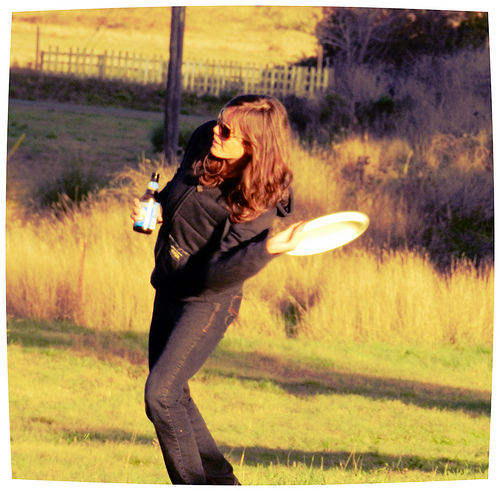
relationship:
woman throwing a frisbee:
[127, 91, 374, 486] [285, 211, 370, 258]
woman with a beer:
[127, 91, 374, 486] [130, 171, 162, 237]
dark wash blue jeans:
[177, 328, 199, 343] [143, 282, 247, 489]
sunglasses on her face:
[210, 114, 249, 141] [205, 113, 243, 162]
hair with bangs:
[189, 89, 295, 223] [213, 104, 252, 132]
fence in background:
[26, 33, 345, 101] [13, 6, 490, 275]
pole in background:
[156, 5, 188, 163] [13, 6, 490, 275]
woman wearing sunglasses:
[127, 91, 374, 486] [210, 114, 249, 141]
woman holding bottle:
[127, 91, 374, 486] [130, 171, 162, 237]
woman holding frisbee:
[127, 91, 374, 486] [285, 211, 370, 258]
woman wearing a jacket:
[127, 91, 374, 486] [148, 118, 282, 303]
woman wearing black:
[127, 91, 374, 486] [189, 189, 232, 262]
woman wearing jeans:
[127, 91, 374, 486] [143, 282, 247, 489]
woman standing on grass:
[127, 91, 374, 486] [7, 311, 498, 483]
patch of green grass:
[7, 98, 158, 193] [7, 311, 498, 483]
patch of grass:
[7, 98, 158, 193] [7, 311, 498, 483]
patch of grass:
[183, 319, 486, 476] [7, 311, 498, 483]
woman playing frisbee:
[127, 91, 374, 486] [285, 211, 370, 258]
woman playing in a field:
[127, 91, 374, 486] [28, 106, 470, 478]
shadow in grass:
[217, 438, 485, 477] [7, 311, 498, 483]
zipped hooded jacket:
[141, 171, 213, 270] [148, 118, 282, 303]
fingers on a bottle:
[129, 196, 143, 226] [130, 171, 162, 237]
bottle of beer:
[130, 171, 162, 237] [140, 167, 170, 241]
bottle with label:
[130, 171, 162, 237] [132, 198, 166, 233]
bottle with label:
[130, 171, 162, 237] [144, 179, 162, 191]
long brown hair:
[247, 124, 292, 235] [189, 89, 295, 223]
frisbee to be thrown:
[285, 211, 370, 258] [236, 156, 378, 299]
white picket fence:
[325, 232, 337, 244] [26, 33, 345, 101]